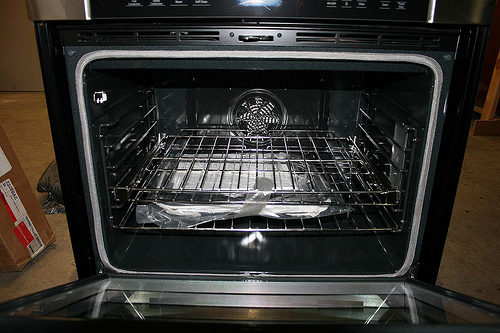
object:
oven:
[0, 1, 498, 332]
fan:
[224, 94, 289, 148]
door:
[0, 268, 499, 332]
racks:
[110, 128, 399, 196]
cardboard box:
[0, 123, 63, 278]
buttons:
[124, 0, 146, 11]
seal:
[70, 50, 443, 282]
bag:
[31, 159, 69, 216]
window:
[16, 288, 480, 331]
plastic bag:
[126, 146, 354, 230]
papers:
[170, 153, 298, 193]